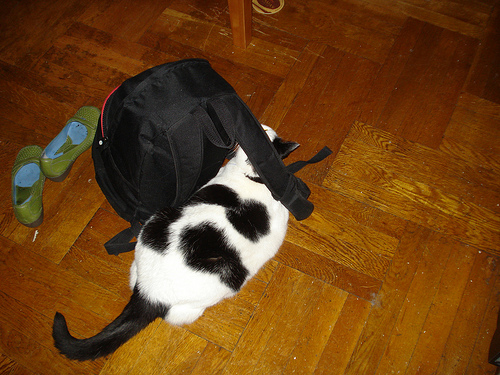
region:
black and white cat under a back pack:
[52, 121, 289, 361]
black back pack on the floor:
[93, 56, 312, 254]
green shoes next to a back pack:
[12, 106, 104, 223]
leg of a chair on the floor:
[229, 0, 251, 50]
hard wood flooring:
[8, 2, 499, 374]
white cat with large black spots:
[52, 120, 297, 357]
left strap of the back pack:
[193, 66, 311, 223]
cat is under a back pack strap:
[51, 114, 303, 354]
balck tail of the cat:
[51, 286, 165, 360]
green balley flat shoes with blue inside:
[14, 101, 101, 221]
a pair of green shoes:
[9, 103, 96, 232]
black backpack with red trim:
[94, 65, 244, 194]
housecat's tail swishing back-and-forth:
[47, 291, 162, 364]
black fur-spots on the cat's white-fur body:
[139, 197, 274, 288]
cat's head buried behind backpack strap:
[209, 81, 318, 216]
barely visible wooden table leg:
[229, 0, 254, 51]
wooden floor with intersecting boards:
[336, 0, 498, 373]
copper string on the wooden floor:
[251, 0, 289, 14]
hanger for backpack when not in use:
[194, 97, 236, 145]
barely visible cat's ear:
[274, 139, 297, 152]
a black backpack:
[114, 88, 229, 172]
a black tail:
[51, 318, 158, 355]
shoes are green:
[6, 108, 96, 218]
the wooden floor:
[322, 118, 498, 374]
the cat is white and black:
[123, 211, 291, 317]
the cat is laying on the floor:
[116, 222, 241, 322]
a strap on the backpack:
[171, 132, 204, 185]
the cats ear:
[275, 135, 296, 153]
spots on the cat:
[187, 223, 248, 283]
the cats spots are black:
[139, 224, 181, 254]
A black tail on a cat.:
[50, 272, 175, 372]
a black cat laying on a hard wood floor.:
[69, 52, 316, 268]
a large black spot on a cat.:
[140, 163, 272, 265]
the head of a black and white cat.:
[224, 109, 302, 170]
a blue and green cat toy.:
[7, 105, 112, 246]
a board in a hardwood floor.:
[309, 273, 381, 373]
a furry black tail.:
[44, 270, 171, 362]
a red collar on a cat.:
[71, 62, 138, 153]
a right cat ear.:
[271, 120, 303, 157]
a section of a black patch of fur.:
[227, 193, 279, 244]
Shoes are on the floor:
[10, 106, 95, 216]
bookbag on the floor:
[100, 55, 310, 245]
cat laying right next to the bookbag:
[40, 125, 305, 360]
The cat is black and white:
[45, 125, 300, 355]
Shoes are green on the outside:
[15, 102, 100, 223]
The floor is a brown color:
[0, 5, 492, 370]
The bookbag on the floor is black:
[94, 59, 331, 256]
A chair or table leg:
[224, 0, 271, 47]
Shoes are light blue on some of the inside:
[12, 106, 99, 225]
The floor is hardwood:
[10, 8, 497, 370]